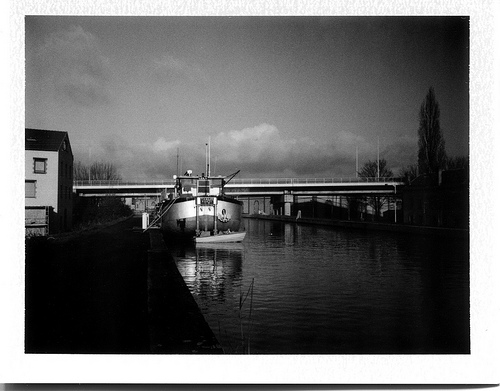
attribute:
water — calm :
[169, 212, 471, 353]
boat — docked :
[155, 176, 247, 235]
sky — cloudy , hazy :
[200, 37, 340, 116]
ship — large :
[155, 136, 247, 244]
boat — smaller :
[198, 225, 245, 243]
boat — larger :
[141, 126, 249, 228]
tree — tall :
[411, 87, 451, 188]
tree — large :
[356, 154, 395, 182]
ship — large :
[136, 126, 265, 261]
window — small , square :
[30, 153, 51, 177]